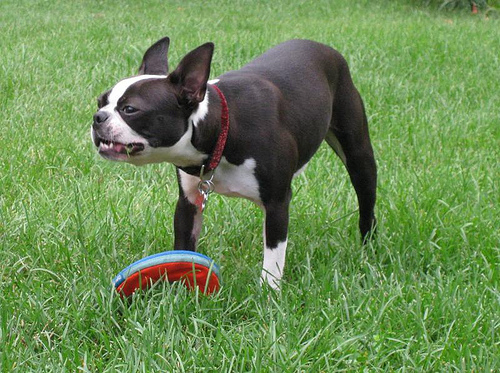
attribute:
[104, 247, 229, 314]
frisbee — red, blue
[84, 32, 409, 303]
dog — black, white, brown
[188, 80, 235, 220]
collar — red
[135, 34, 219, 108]
ears — pointy, black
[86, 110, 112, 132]
nose — black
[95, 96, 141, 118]
eyes — open, dark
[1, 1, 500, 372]
grass — tall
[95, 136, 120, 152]
teeth — white